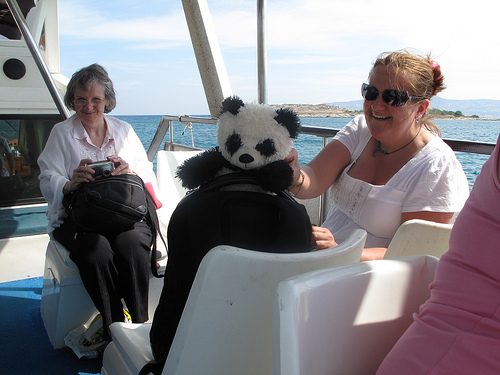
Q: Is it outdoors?
A: Yes, it is outdoors.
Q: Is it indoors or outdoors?
A: It is outdoors.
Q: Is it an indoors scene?
A: No, it is outdoors.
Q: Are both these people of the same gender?
A: Yes, all the people are female.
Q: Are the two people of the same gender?
A: Yes, all the people are female.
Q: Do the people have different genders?
A: No, all the people are female.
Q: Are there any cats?
A: No, there are no cats.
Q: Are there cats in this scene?
A: No, there are no cats.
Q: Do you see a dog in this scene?
A: No, there are no dogs.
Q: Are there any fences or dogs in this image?
A: No, there are no dogs or fences.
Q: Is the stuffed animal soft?
A: Yes, the stuffed animal is soft.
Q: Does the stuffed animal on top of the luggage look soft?
A: Yes, the stuffed animal is soft.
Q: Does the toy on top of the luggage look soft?
A: Yes, the stuffed animal is soft.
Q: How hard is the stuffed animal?
A: The stuffed animal is soft.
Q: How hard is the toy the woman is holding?
A: The stuffed animal is soft.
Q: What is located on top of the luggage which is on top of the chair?
A: The stuffed animal is on top of the luggage.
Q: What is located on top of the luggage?
A: The stuffed animal is on top of the luggage.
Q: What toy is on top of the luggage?
A: The toy is a stuffed animal.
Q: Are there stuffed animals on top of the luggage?
A: Yes, there is a stuffed animal on top of the luggage.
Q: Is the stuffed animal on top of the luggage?
A: Yes, the stuffed animal is on top of the luggage.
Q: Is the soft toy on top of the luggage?
A: Yes, the stuffed animal is on top of the luggage.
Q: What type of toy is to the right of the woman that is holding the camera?
A: The toy is a stuffed animal.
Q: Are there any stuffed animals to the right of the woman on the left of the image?
A: Yes, there is a stuffed animal to the right of the woman.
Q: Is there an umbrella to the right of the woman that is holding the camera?
A: No, there is a stuffed animal to the right of the woman.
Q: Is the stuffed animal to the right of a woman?
A: Yes, the stuffed animal is to the right of a woman.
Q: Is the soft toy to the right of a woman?
A: Yes, the stuffed animal is to the right of a woman.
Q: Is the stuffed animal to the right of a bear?
A: No, the stuffed animal is to the right of a woman.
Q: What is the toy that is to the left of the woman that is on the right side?
A: The toy is a stuffed animal.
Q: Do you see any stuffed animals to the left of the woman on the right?
A: Yes, there is a stuffed animal to the left of the woman.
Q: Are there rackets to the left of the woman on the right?
A: No, there is a stuffed animal to the left of the woman.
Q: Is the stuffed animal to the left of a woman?
A: Yes, the stuffed animal is to the left of a woman.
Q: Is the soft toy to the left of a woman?
A: Yes, the stuffed animal is to the left of a woman.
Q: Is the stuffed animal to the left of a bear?
A: No, the stuffed animal is to the left of a woman.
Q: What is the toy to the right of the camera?
A: The toy is a stuffed animal.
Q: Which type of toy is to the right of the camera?
A: The toy is a stuffed animal.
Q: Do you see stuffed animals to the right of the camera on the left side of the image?
A: Yes, there is a stuffed animal to the right of the camera.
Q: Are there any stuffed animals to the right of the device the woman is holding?
A: Yes, there is a stuffed animal to the right of the camera.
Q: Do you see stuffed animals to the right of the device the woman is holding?
A: Yes, there is a stuffed animal to the right of the camera.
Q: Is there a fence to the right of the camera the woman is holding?
A: No, there is a stuffed animal to the right of the camera.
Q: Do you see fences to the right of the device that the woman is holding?
A: No, there is a stuffed animal to the right of the camera.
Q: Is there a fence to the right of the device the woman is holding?
A: No, there is a stuffed animal to the right of the camera.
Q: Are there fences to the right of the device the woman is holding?
A: No, there is a stuffed animal to the right of the camera.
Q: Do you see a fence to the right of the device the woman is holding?
A: No, there is a stuffed animal to the right of the camera.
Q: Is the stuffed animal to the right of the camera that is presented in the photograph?
A: Yes, the stuffed animal is to the right of the camera.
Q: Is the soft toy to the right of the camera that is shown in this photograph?
A: Yes, the stuffed animal is to the right of the camera.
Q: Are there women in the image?
A: Yes, there is a woman.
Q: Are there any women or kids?
A: Yes, there is a woman.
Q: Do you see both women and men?
A: No, there is a woman but no men.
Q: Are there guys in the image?
A: No, there are no guys.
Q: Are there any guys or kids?
A: No, there are no guys or kids.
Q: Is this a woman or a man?
A: This is a woman.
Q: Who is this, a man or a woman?
A: This is a woman.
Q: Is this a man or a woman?
A: This is a woman.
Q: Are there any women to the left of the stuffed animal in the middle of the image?
A: Yes, there is a woman to the left of the stuffed animal.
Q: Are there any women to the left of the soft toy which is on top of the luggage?
A: Yes, there is a woman to the left of the stuffed animal.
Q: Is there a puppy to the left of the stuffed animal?
A: No, there is a woman to the left of the stuffed animal.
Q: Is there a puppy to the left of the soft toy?
A: No, there is a woman to the left of the stuffed animal.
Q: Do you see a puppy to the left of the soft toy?
A: No, there is a woman to the left of the stuffed animal.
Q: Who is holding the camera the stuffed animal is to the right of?
A: The woman is holding the camera.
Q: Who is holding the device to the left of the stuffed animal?
A: The woman is holding the camera.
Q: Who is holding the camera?
A: The woman is holding the camera.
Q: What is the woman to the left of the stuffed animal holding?
A: The woman is holding the camera.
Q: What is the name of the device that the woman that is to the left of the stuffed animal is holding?
A: The device is a camera.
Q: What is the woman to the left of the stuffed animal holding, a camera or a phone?
A: The woman is holding a camera.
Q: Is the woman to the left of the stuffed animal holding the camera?
A: Yes, the woman is holding the camera.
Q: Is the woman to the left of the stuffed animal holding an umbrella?
A: No, the woman is holding the camera.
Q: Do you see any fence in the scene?
A: No, there are no fences.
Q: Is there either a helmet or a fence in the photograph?
A: No, there are no fences or helmets.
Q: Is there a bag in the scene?
A: Yes, there is a bag.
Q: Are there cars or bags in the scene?
A: Yes, there is a bag.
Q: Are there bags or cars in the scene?
A: Yes, there is a bag.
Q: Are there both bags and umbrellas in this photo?
A: No, there is a bag but no umbrellas.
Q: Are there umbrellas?
A: No, there are no umbrellas.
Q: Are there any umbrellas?
A: No, there are no umbrellas.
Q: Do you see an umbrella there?
A: No, there are no umbrellas.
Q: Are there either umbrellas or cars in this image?
A: No, there are no umbrellas or cars.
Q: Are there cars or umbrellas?
A: No, there are no umbrellas or cars.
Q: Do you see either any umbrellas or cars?
A: No, there are no umbrellas or cars.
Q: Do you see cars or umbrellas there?
A: No, there are no umbrellas or cars.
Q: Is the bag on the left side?
A: Yes, the bag is on the left of the image.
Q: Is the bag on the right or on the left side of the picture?
A: The bag is on the left of the image.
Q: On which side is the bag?
A: The bag is on the left of the image.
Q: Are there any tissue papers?
A: No, there are no tissue papers.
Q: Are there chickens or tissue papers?
A: No, there are no tissue papers or chickens.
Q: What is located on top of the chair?
A: The luggage is on top of the chair.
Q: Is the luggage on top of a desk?
A: No, the luggage is on top of the chair.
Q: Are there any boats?
A: Yes, there is a boat.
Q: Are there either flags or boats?
A: Yes, there is a boat.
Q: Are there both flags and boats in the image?
A: No, there is a boat but no flags.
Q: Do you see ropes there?
A: No, there are no ropes.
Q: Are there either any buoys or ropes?
A: No, there are no ropes or buoys.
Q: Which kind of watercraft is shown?
A: The watercraft is a boat.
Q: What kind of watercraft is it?
A: The watercraft is a boat.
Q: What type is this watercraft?
A: This is a boat.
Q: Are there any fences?
A: No, there are no fences.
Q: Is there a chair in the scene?
A: Yes, there is a chair.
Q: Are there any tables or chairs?
A: Yes, there is a chair.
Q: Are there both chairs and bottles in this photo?
A: No, there is a chair but no bottles.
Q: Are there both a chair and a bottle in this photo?
A: No, there is a chair but no bottles.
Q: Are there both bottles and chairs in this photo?
A: No, there is a chair but no bottles.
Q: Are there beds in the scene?
A: No, there are no beds.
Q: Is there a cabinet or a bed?
A: No, there are no beds or cabinets.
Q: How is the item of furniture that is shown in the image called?
A: The piece of furniture is a chair.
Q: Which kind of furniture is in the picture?
A: The furniture is a chair.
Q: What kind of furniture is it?
A: The piece of furniture is a chair.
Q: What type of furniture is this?
A: This is a chair.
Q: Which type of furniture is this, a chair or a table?
A: This is a chair.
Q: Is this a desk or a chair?
A: This is a chair.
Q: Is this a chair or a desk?
A: This is a chair.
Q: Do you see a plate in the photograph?
A: No, there are no plates.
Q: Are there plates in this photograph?
A: No, there are no plates.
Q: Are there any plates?
A: No, there are no plates.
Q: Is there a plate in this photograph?
A: No, there are no plates.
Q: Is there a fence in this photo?
A: No, there are no fences.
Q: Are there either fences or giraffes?
A: No, there are no fences or giraffes.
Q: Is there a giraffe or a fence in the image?
A: No, there are no fences or giraffes.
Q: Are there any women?
A: Yes, there is a woman.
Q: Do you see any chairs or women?
A: Yes, there is a woman.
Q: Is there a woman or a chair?
A: Yes, there is a woman.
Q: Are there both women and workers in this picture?
A: No, there is a woman but no workers.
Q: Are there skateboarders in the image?
A: No, there are no skateboarders.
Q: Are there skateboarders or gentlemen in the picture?
A: No, there are no skateboarders or gentlemen.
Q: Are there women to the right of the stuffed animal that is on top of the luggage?
A: Yes, there is a woman to the right of the stuffed animal.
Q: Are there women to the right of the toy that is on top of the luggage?
A: Yes, there is a woman to the right of the stuffed animal.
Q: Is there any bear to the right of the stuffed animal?
A: No, there is a woman to the right of the stuffed animal.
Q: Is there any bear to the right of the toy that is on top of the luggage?
A: No, there is a woman to the right of the stuffed animal.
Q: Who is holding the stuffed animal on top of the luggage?
A: The woman is holding the stuffed animal.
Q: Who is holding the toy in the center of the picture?
A: The woman is holding the stuffed animal.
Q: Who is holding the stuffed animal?
A: The woman is holding the stuffed animal.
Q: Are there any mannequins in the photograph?
A: No, there are no mannequins.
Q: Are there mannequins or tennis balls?
A: No, there are no mannequins or tennis balls.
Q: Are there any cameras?
A: Yes, there is a camera.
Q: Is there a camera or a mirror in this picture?
A: Yes, there is a camera.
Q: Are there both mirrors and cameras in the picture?
A: No, there is a camera but no mirrors.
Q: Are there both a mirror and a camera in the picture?
A: No, there is a camera but no mirrors.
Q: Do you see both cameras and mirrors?
A: No, there is a camera but no mirrors.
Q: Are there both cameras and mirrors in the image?
A: No, there is a camera but no mirrors.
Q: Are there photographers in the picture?
A: No, there are no photographers.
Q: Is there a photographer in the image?
A: No, there are no photographers.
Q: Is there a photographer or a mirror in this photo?
A: No, there are no photographers or mirrors.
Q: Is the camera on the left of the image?
A: Yes, the camera is on the left of the image.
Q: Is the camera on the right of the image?
A: No, the camera is on the left of the image.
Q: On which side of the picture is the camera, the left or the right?
A: The camera is on the left of the image.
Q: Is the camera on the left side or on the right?
A: The camera is on the left of the image.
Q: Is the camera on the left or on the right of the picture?
A: The camera is on the left of the image.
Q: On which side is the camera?
A: The camera is on the left of the image.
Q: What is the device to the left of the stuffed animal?
A: The device is a camera.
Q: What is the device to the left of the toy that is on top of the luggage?
A: The device is a camera.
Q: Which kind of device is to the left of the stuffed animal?
A: The device is a camera.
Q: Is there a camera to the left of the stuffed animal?
A: Yes, there is a camera to the left of the stuffed animal.